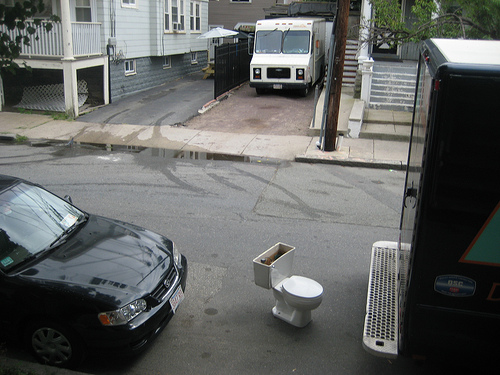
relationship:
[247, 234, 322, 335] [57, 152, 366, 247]
toilet on street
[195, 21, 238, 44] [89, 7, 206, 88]
umbrella beside house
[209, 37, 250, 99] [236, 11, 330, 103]
railings beside truck